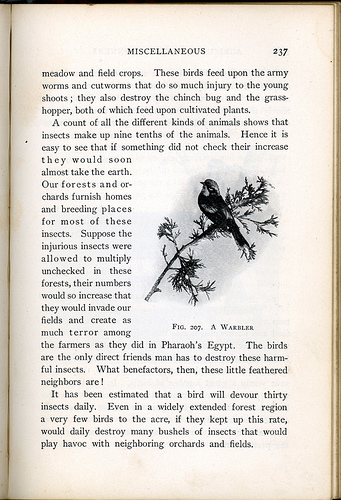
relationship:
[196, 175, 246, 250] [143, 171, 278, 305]
bird on branch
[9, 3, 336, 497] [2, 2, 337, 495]
page from book